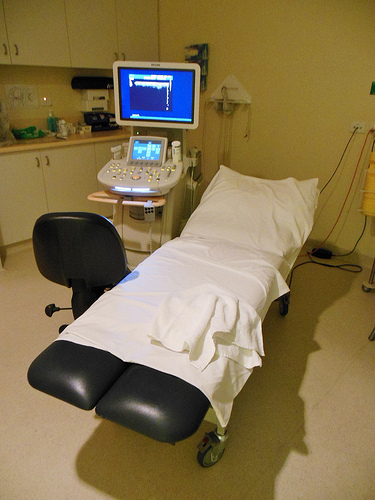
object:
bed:
[25, 160, 321, 469]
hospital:
[0, 0, 375, 499]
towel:
[143, 280, 267, 371]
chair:
[31, 209, 131, 333]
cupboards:
[0, 138, 98, 254]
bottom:
[30, 210, 117, 232]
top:
[36, 2, 176, 18]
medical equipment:
[85, 60, 204, 252]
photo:
[0, 0, 375, 499]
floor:
[287, 371, 375, 500]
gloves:
[183, 42, 202, 62]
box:
[183, 43, 209, 61]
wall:
[255, 0, 364, 125]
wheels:
[196, 430, 226, 468]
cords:
[317, 126, 359, 197]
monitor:
[112, 60, 201, 130]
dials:
[112, 168, 116, 173]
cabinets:
[63, 0, 163, 71]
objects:
[60, 118, 68, 137]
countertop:
[0, 124, 128, 153]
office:
[29, 23, 375, 320]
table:
[89, 178, 183, 250]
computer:
[96, 60, 201, 197]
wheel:
[277, 289, 290, 316]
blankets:
[146, 230, 291, 289]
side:
[6, 64, 120, 88]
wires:
[310, 214, 368, 259]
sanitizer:
[47, 116, 57, 134]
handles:
[14, 42, 20, 56]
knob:
[44, 303, 60, 319]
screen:
[119, 69, 195, 120]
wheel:
[58, 323, 69, 334]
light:
[111, 186, 162, 194]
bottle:
[47, 109, 58, 132]